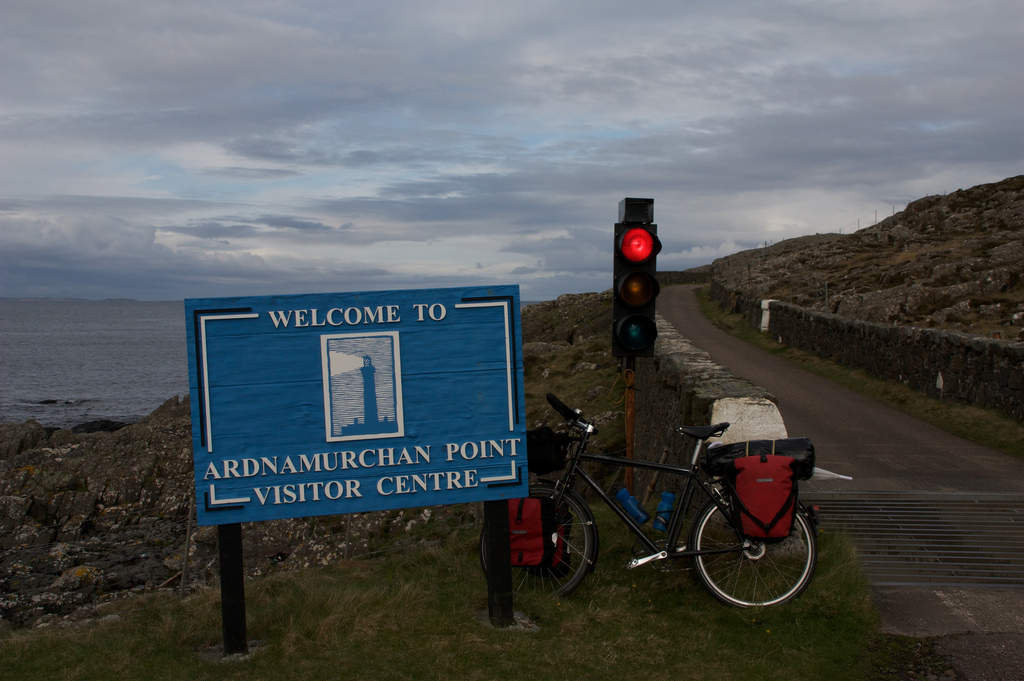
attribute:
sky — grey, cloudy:
[25, 121, 786, 422]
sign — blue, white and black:
[180, 285, 530, 534]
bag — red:
[717, 448, 806, 537]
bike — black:
[535, 401, 825, 613]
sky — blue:
[4, 3, 992, 302]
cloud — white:
[158, 139, 288, 170]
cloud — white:
[264, 154, 515, 217]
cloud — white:
[505, 18, 832, 131]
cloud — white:
[646, 175, 910, 240]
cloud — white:
[4, 147, 179, 200]